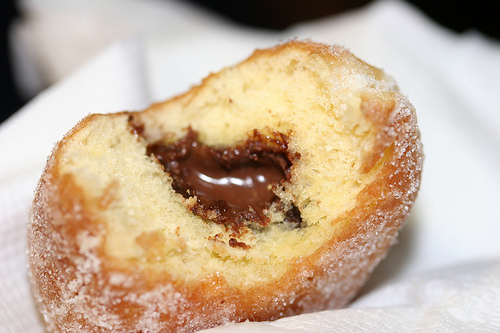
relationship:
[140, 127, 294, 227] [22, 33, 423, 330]
chocolate in bread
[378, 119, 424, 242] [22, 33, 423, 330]
sugar on bread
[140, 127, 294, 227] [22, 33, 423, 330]
chocolate of bread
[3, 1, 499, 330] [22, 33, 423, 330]
napkin under bread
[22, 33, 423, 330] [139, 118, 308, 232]
bread with chocolate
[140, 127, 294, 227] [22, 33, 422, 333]
chocolate inside bread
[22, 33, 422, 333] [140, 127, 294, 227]
bread has chocolate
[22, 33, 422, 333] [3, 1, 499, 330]
bread on napkin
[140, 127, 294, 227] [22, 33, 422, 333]
chocolate on bread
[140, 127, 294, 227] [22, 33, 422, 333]
chocolate in center of bread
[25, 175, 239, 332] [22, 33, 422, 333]
sugar on bread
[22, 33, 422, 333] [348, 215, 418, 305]
bread casting shadow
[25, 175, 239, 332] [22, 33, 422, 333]
sugar on outside of bread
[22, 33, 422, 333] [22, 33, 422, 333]
bread in bread